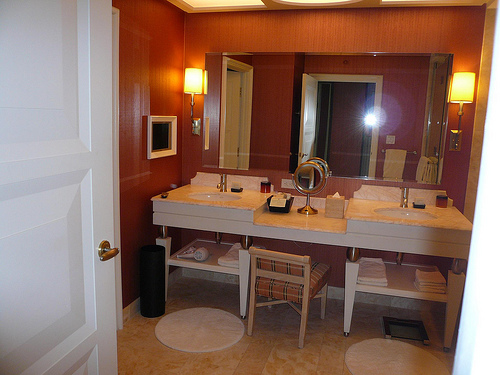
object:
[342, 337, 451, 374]
round rug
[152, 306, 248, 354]
rug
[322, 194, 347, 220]
tissue box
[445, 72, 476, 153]
lamp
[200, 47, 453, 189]
mirror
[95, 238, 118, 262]
handle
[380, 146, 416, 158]
rack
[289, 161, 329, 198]
mirror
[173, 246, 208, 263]
blow dryer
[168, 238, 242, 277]
shelf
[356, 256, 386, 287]
towel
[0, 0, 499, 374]
room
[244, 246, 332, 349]
chair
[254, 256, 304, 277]
cushions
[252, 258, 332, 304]
cushions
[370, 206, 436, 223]
sink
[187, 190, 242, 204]
sink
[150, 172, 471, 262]
counter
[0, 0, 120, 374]
door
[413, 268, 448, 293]
towels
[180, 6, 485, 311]
wall